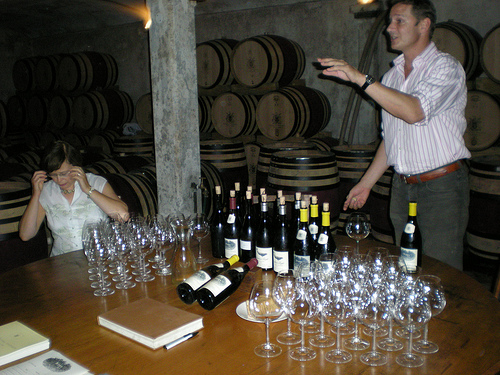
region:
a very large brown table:
[1, 218, 496, 374]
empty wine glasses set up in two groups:
[82, 211, 444, 368]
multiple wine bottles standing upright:
[176, 182, 433, 274]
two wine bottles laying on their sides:
[176, 253, 258, 309]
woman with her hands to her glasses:
[30, 142, 93, 200]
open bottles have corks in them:
[210, 180, 334, 276]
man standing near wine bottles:
[203, 1, 473, 273]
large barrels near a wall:
[1, 18, 496, 280]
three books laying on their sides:
[0, 293, 212, 373]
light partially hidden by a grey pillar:
[141, 0, 201, 221]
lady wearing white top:
[15, 129, 153, 266]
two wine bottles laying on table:
[142, 231, 272, 319]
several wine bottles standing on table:
[196, 168, 365, 293]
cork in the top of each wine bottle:
[192, 171, 354, 281]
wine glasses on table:
[238, 256, 478, 373]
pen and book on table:
[84, 283, 235, 373]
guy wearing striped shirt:
[323, 6, 493, 261]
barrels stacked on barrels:
[202, 30, 387, 220]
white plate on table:
[230, 285, 308, 334]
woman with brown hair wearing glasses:
[18, 136, 130, 226]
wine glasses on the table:
[245, 213, 450, 369]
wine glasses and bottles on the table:
[73, 178, 449, 372]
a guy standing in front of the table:
[313, 2, 474, 277]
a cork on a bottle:
[228, 189, 237, 196]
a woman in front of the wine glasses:
[16, 138, 154, 298]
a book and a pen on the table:
[95, 294, 205, 361]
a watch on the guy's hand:
[358, 73, 376, 91]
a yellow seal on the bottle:
[407, 201, 417, 217]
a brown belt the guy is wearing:
[393, 158, 465, 185]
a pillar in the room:
[143, 0, 215, 215]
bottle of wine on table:
[195, 256, 262, 315]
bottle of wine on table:
[400, 196, 428, 277]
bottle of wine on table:
[319, 199, 338, 259]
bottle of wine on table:
[293, 193, 312, 275]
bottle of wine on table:
[273, 189, 296, 281]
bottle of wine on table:
[250, 190, 277, 274]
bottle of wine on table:
[237, 187, 259, 266]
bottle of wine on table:
[220, 187, 242, 263]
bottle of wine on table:
[207, 182, 227, 262]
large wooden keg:
[225, 30, 314, 93]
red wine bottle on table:
[208, 176, 222, 268]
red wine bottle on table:
[176, 250, 206, 294]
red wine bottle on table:
[213, 279, 249, 326]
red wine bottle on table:
[368, 189, 438, 274]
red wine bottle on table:
[296, 205, 319, 287]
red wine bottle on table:
[273, 196, 290, 270]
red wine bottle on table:
[256, 183, 276, 270]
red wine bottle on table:
[305, 192, 320, 227]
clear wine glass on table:
[395, 285, 428, 350]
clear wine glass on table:
[236, 281, 277, 351]